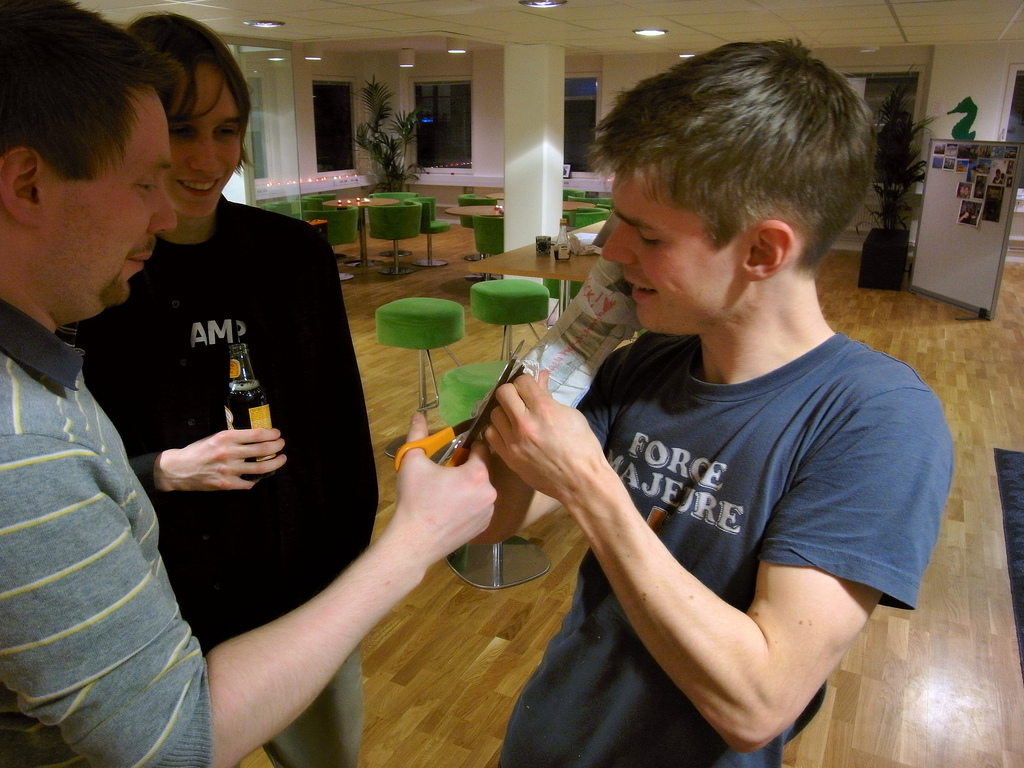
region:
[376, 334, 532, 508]
scissors in man's hand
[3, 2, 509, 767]
man cutting piece of paper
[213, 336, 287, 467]
bottle in man's hand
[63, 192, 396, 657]
man wearing a shirt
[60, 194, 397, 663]
man's shirt is black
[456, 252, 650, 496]
cast on man's arm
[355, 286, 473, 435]
stool behind man in middle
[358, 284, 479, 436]
stool in room is green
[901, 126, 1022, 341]
tall white board with pictures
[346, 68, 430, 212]
large plant in corner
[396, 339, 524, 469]
the scissors have an orange handle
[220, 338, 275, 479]
the dark liquid in the bottle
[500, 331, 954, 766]
the shirt is blue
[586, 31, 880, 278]
the hair is ash brown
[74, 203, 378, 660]
the jacket is black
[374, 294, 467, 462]
the stool has a green seat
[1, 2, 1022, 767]
the wood floor in the room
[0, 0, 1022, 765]
the green tree in the corner of the room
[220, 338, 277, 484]
the labels on the bottle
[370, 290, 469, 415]
green stools in a large game room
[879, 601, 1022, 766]
light glare on the wood floor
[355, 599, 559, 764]
parquet wood floors in the game room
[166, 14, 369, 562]
young man smiling and holding a bottle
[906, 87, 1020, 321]
seahorse figurine on a counter display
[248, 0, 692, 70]
recessed lighting in the ceiling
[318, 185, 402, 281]
a board game on a round table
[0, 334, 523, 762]
man with a green shirt holding orange scissors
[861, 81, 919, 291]
indoor tree in a black planter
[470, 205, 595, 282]
wooden table with condiments on it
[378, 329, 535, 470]
Man holding scissors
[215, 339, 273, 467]
young man holding beer bottle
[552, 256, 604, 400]
young man with cast on arm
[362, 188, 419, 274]
green barstool type chairs anchored to floor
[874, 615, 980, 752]
light colored hardwood floors in room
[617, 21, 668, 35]
room has recessed lighting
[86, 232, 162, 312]
the man has short facial hair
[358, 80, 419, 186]
potted trees for decoration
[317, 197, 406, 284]
Tables to use for any activity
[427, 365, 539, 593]
furry green chair by the white pillar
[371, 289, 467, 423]
furry green chair by the white pillar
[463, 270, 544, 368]
furry green chair by the white pillar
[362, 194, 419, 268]
furry green chair by the white pillar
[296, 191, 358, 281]
furry green chair by the white pillar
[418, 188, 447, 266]
furry green chair by the white pillar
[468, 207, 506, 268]
furry green chair by the white pillar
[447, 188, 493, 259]
furry green chair by the white pillar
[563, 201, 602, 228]
furry green chair by the white pillar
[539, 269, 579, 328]
furry green chair by the white pillar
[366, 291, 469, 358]
Green seat at table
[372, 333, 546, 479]
Person using scissors to cut something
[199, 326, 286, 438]
Drink in a glass bottle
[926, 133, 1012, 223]
Pictures on a board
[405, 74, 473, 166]
Window in a room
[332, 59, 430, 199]
Plant in the corner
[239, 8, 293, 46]
Light on the ceiling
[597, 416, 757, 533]
Writing on a shirt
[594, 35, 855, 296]
Short haircut on man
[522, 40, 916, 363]
head of the boy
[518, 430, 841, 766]
arm of the man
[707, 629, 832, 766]
elbow of the man